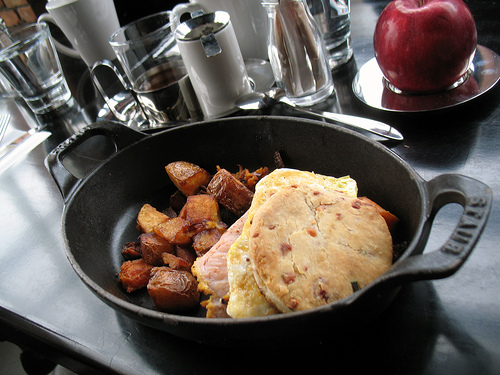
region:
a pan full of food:
[40, 115, 472, 325]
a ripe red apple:
[362, 4, 498, 90]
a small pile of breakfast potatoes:
[135, 171, 222, 301]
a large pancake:
[246, 177, 385, 308]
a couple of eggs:
[226, 160, 324, 328]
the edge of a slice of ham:
[187, 158, 262, 322]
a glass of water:
[80, 18, 197, 117]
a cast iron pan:
[30, 105, 490, 332]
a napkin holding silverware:
[2, 105, 47, 191]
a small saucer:
[355, 24, 498, 126]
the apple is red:
[369, 3, 477, 103]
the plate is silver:
[347, 73, 450, 120]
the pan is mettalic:
[63, 116, 485, 331]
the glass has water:
[13, 24, 73, 112]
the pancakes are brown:
[251, 186, 386, 321]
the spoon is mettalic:
[246, 84, 414, 142]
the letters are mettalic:
[450, 190, 490, 260]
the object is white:
[167, 38, 264, 112]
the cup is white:
[48, 6, 135, 75]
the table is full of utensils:
[21, 20, 460, 365]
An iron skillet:
[43, 114, 492, 327]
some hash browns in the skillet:
[112, 161, 248, 291]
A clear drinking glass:
[0, 21, 71, 111]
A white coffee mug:
[35, 0, 127, 75]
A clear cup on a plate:
[91, 8, 194, 133]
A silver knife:
[0, 123, 50, 160]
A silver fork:
[0, 112, 11, 141]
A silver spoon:
[236, 91, 402, 141]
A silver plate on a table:
[353, 41, 495, 113]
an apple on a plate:
[371, 0, 478, 88]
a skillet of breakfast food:
[37, 110, 493, 347]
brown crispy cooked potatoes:
[117, 149, 264, 303]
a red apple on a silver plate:
[345, 0, 498, 118]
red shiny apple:
[371, 2, 477, 94]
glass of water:
[101, 9, 213, 129]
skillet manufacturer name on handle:
[440, 176, 499, 274]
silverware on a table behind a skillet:
[231, 86, 405, 144]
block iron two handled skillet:
[35, 108, 496, 345]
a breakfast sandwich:
[192, 162, 393, 328]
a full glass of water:
[2, 21, 77, 117]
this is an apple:
[371, 1, 481, 86]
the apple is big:
[375, 5, 480, 92]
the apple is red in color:
[377, 18, 420, 55]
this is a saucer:
[356, 75, 377, 94]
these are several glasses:
[13, 10, 336, 93]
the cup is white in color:
[64, 8, 89, 25]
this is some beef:
[155, 172, 217, 234]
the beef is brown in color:
[128, 265, 181, 288]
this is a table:
[5, 205, 54, 301]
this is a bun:
[213, 235, 356, 282]